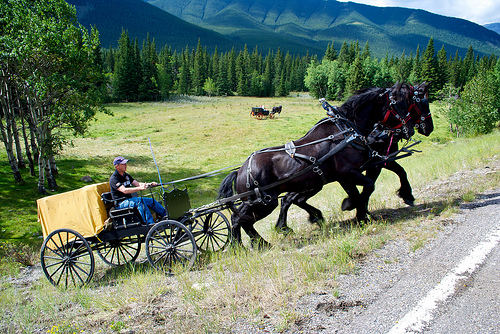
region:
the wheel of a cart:
[141, 220, 199, 277]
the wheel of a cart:
[34, 227, 96, 294]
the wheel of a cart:
[182, 212, 231, 254]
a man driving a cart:
[106, 153, 170, 238]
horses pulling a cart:
[215, 79, 438, 245]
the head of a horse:
[351, 84, 413, 144]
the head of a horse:
[402, 82, 436, 139]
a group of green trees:
[132, 36, 300, 96]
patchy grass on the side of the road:
[244, 234, 367, 283]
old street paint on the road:
[395, 230, 497, 326]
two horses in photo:
[219, 57, 477, 216]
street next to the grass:
[393, 263, 493, 318]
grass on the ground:
[133, 252, 238, 324]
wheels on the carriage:
[16, 202, 208, 310]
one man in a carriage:
[86, 139, 173, 228]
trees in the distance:
[135, 41, 262, 101]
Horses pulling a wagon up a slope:
[36, 78, 438, 290]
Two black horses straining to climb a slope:
[219, 77, 436, 251]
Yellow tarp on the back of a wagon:
[35, 180, 113, 248]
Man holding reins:
[108, 154, 167, 226]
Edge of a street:
[338, 179, 498, 332]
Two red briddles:
[378, 99, 432, 131]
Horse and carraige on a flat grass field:
[247, 103, 285, 121]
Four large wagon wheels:
[41, 207, 233, 289]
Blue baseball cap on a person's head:
[112, 156, 130, 173]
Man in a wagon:
[35, 153, 230, 288]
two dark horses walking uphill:
[228, 80, 431, 248]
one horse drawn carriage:
[15, 78, 451, 300]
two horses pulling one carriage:
[35, 83, 438, 290]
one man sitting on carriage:
[28, 139, 240, 287]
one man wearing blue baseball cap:
[111, 152, 131, 176]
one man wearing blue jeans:
[111, 157, 166, 226]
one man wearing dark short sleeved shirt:
[109, 154, 149, 203]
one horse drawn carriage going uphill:
[23, 82, 433, 293]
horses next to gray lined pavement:
[219, 72, 496, 326]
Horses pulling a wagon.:
[38, 79, 435, 289]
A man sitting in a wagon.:
[110, 156, 165, 223]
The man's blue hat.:
[112, 154, 129, 165]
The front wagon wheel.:
[147, 218, 197, 279]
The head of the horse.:
[381, 82, 412, 143]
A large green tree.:
[116, 31, 142, 102]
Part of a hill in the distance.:
[232, 4, 306, 38]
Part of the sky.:
[467, 5, 491, 18]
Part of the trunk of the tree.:
[38, 158, 48, 194]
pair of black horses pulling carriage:
[220, 79, 443, 254]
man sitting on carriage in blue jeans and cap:
[103, 153, 170, 230]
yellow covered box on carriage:
[34, 180, 114, 250]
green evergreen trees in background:
[93, 34, 495, 110]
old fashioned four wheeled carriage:
[43, 179, 237, 286]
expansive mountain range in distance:
[88, 0, 498, 69]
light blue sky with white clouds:
[373, 0, 499, 33]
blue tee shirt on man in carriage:
[108, 173, 133, 201]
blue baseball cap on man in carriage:
[115, 156, 128, 170]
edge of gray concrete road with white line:
[329, 179, 497, 328]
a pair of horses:
[219, 71, 442, 248]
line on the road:
[391, 212, 494, 332]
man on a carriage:
[98, 145, 169, 225]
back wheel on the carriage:
[18, 223, 99, 290]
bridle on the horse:
[368, 80, 423, 147]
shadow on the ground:
[390, 176, 497, 233]